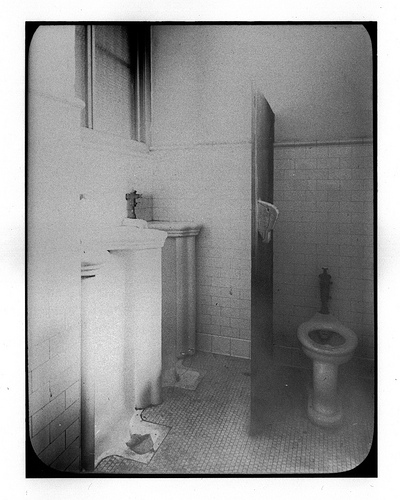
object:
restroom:
[28, 23, 376, 475]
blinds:
[85, 25, 150, 144]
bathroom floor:
[94, 350, 373, 479]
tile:
[209, 285, 232, 300]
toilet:
[297, 267, 360, 427]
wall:
[26, 20, 372, 474]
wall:
[152, 150, 246, 360]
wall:
[152, 31, 365, 137]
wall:
[32, 107, 156, 405]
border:
[27, 22, 379, 477]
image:
[27, 22, 374, 476]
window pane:
[89, 26, 142, 143]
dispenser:
[256, 198, 279, 243]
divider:
[249, 81, 278, 436]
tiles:
[194, 425, 200, 432]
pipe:
[319, 267, 333, 314]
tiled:
[29, 116, 390, 473]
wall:
[19, 23, 185, 489]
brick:
[283, 190, 297, 201]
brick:
[340, 201, 353, 213]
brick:
[316, 242, 339, 254]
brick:
[295, 157, 318, 169]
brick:
[274, 158, 294, 171]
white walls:
[148, 29, 371, 141]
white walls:
[272, 144, 379, 353]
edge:
[272, 139, 370, 146]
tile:
[316, 222, 340, 235]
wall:
[251, 86, 276, 371]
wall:
[41, 237, 80, 419]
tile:
[283, 252, 306, 264]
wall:
[28, 28, 170, 457]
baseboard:
[195, 332, 213, 353]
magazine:
[27, 25, 373, 476]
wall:
[24, 23, 372, 470]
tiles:
[249, 457, 256, 464]